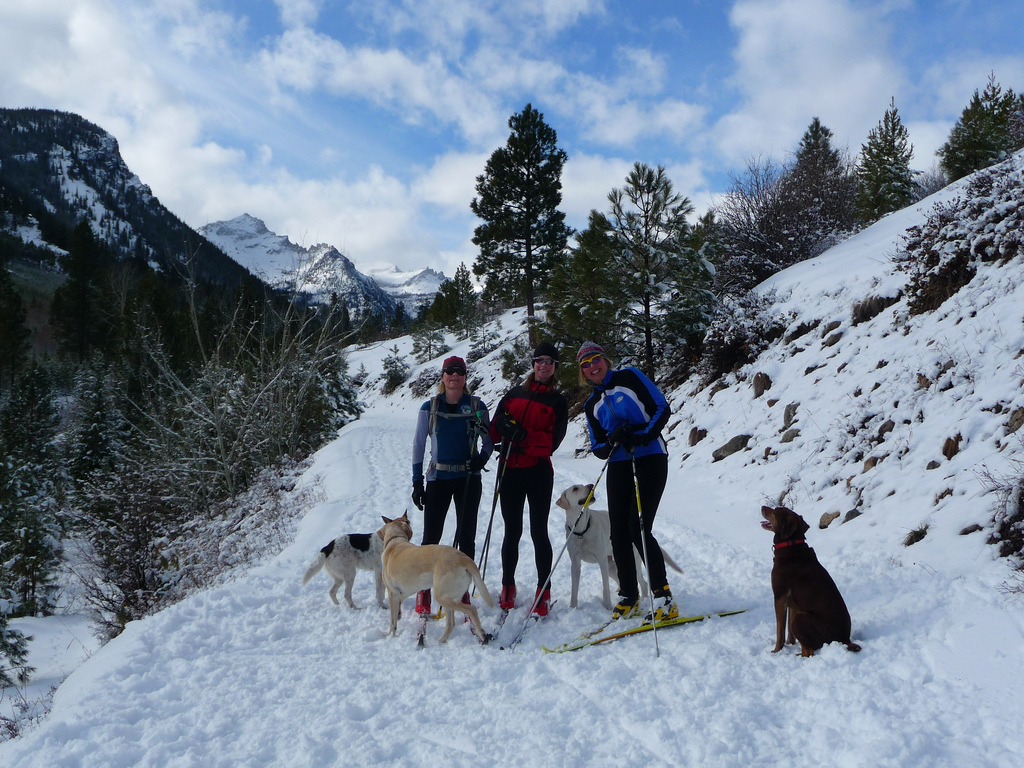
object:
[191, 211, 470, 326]
mountains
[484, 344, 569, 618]
skier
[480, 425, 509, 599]
poles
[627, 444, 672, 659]
poles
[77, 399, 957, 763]
footprints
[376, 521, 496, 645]
dog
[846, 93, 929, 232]
trees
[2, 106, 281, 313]
mountain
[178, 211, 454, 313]
mountain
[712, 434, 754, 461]
rocks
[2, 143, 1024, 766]
snow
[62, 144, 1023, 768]
hills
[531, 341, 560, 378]
head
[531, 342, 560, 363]
hat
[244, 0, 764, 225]
cloud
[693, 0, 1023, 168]
cloud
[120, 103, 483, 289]
cloud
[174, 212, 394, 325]
mountain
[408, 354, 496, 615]
person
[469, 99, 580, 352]
pine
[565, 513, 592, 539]
collar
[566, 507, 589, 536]
neck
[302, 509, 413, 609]
dog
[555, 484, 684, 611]
dog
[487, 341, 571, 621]
people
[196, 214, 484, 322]
snow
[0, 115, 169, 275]
snow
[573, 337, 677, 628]
person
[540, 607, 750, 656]
ski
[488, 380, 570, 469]
jacket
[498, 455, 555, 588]
pants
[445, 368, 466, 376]
sunglasses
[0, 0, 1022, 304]
sky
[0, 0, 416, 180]
cloud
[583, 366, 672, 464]
jacket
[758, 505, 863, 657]
dog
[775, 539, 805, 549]
collar